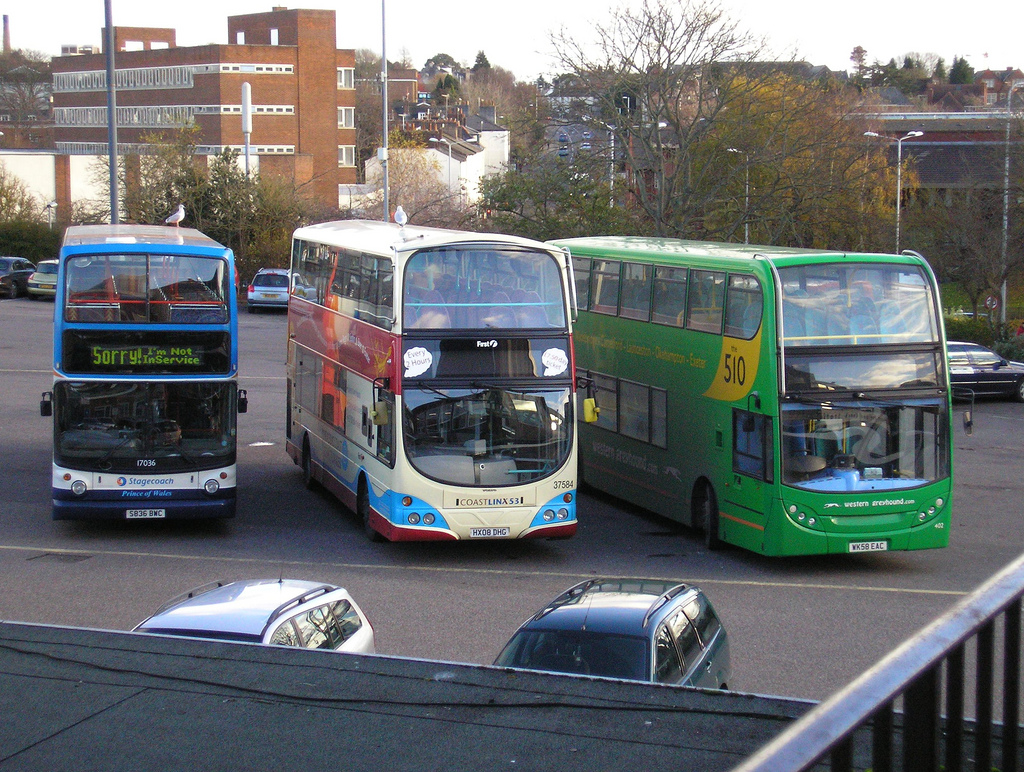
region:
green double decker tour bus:
[576, 233, 953, 559]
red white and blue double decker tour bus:
[277, 214, 581, 547]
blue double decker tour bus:
[46, 224, 239, 529]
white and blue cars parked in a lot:
[125, 571, 739, 711]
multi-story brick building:
[51, 6, 358, 215]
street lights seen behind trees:
[576, 104, 1016, 250]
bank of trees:
[485, 0, 893, 248]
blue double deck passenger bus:
[18, 214, 260, 537]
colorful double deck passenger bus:
[282, 219, 595, 546]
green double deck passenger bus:
[603, 229, 958, 566]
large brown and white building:
[64, 8, 365, 189]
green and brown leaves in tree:
[782, 150, 836, 186]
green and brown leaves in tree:
[687, 173, 765, 231]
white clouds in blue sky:
[416, 8, 461, 48]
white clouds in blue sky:
[179, 7, 211, 26]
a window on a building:
[43, 69, 62, 98]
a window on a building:
[72, 59, 83, 95]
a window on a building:
[97, 75, 111, 99]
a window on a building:
[176, 66, 196, 89]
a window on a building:
[59, 107, 61, 123]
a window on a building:
[82, 111, 96, 127]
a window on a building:
[115, 117, 135, 124]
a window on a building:
[158, 110, 172, 129]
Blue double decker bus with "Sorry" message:
[42, 224, 246, 542]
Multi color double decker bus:
[286, 215, 599, 560]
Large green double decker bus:
[547, 233, 978, 569]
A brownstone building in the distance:
[51, 6, 359, 221]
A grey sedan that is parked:
[244, 266, 295, 312]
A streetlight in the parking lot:
[864, 126, 923, 254]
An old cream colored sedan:
[24, 258, 62, 300]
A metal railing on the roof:
[725, 546, 1020, 769]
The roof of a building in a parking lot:
[0, 617, 1021, 767]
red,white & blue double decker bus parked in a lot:
[287, 228, 578, 538]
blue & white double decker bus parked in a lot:
[43, 222, 252, 526]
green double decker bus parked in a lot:
[557, 239, 976, 554]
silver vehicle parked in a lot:
[246, 266, 295, 312]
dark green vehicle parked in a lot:
[492, 569, 731, 684]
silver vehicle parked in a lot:
[135, 578, 380, 655]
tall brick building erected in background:
[58, 0, 356, 230]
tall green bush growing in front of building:
[226, 178, 313, 259]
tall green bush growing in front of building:
[86, 138, 173, 233]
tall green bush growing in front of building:
[0, 175, 45, 253]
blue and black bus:
[41, 195, 266, 556]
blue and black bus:
[41, 198, 276, 554]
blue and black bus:
[36, 193, 267, 571]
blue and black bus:
[33, 198, 272, 544]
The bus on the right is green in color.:
[539, 236, 969, 568]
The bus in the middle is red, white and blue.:
[283, 223, 598, 555]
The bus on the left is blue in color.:
[38, 208, 258, 531]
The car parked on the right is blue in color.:
[491, 576, 732, 700]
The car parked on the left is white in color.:
[127, 573, 372, 666]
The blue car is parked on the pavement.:
[482, 577, 736, 696]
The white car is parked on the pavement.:
[122, 576, 375, 657]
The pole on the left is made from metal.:
[90, 4, 133, 227]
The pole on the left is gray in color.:
[95, 0, 133, 221]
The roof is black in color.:
[2, 621, 1021, 767]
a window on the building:
[192, 76, 199, 90]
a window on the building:
[162, 83, 185, 109]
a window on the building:
[178, 95, 198, 140]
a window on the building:
[267, 59, 291, 105]